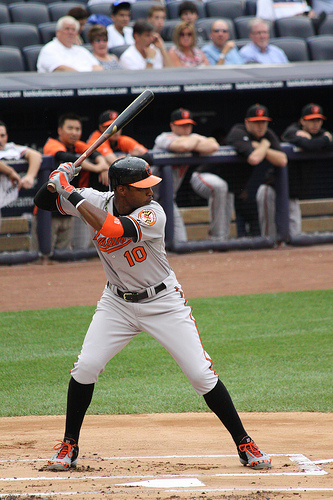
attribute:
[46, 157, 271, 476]
man — at bat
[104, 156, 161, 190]
helmet — black, orange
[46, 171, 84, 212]
glove — gray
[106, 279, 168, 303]
belt — black, dark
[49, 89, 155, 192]
bat — held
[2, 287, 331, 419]
grass — green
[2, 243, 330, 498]
ground — for playing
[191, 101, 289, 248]
players — watching, leaning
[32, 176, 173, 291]
shirt — white, orange, black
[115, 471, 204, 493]
plate — white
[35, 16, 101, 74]
people — watching, sitting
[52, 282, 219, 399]
pants — white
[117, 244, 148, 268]
ten — orange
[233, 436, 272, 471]
shoes — white, gray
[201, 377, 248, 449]
sock — black